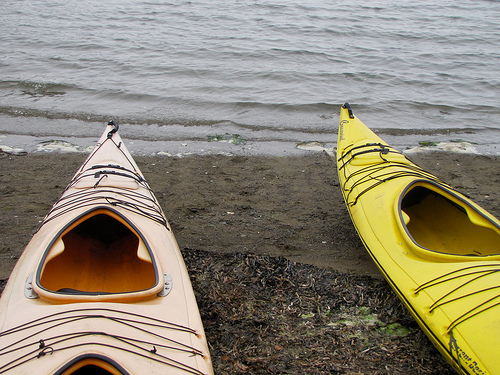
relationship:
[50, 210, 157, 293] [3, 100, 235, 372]
interior of kayak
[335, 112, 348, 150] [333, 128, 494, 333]
name on kayak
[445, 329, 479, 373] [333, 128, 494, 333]
brand name on kayak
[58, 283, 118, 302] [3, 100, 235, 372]
seat in kayak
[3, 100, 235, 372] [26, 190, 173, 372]
kayak for people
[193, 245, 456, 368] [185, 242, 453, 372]
seaweed and debris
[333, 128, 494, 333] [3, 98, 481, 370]
kayak on sandy beach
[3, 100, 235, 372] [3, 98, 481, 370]
kayak on sandy beach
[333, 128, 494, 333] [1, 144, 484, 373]
kayak on shore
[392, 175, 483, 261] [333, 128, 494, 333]
opening on kayak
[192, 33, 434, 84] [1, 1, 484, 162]
waves in ocean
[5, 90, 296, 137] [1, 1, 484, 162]
waves in ocean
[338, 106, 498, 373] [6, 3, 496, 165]
canoe beside water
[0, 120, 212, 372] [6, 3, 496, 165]
canoe beside water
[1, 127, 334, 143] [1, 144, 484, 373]
wave washing on shore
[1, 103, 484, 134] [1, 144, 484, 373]
wave washing on shore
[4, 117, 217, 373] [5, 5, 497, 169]
kayaks by sea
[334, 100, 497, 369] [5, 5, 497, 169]
kayaks by sea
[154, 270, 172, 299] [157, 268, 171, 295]
plate with screws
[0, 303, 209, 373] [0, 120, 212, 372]
rope on canoe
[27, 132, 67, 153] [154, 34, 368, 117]
foam on top of water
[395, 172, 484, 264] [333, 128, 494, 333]
cockpit of kayak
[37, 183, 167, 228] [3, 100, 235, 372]
straps across kayak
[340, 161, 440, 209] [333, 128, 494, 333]
straps across kayak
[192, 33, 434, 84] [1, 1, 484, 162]
waves are in ocean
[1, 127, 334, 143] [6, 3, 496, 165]
wave on water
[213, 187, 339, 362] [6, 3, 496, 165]
dirt beside water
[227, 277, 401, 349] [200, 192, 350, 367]
leaves in sand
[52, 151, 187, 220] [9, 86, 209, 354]
ties on a canoe